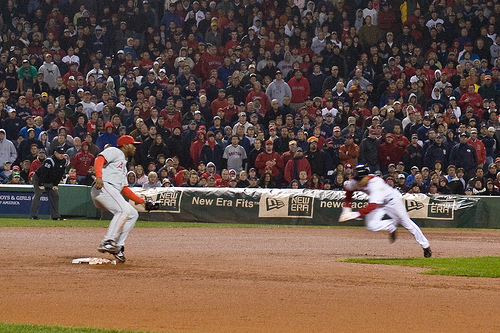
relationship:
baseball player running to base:
[338, 163, 433, 258] [71, 246, 118, 275]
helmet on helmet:
[351, 164, 371, 181] [351, 164, 371, 181]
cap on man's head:
[116, 135, 141, 147] [116, 131, 139, 158]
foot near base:
[94, 239, 130, 268] [67, 256, 114, 270]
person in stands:
[282, 138, 316, 188] [4, 1, 497, 230]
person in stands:
[257, 146, 279, 188] [4, 1, 497, 230]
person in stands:
[220, 136, 250, 172] [4, 1, 497, 230]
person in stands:
[260, 65, 299, 125] [4, 1, 497, 230]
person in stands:
[283, 58, 318, 108] [4, 1, 497, 230]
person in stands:
[307, 62, 329, 105] [63, 8, 474, 175]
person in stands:
[453, 79, 479, 107] [6, 6, 490, 191]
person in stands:
[35, 49, 65, 100] [16, 11, 467, 181]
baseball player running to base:
[338, 163, 433, 258] [74, 250, 125, 269]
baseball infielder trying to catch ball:
[90, 134, 147, 263] [258, 93, 285, 111]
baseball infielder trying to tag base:
[90, 134, 147, 263] [69, 250, 122, 270]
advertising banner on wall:
[61, 180, 482, 230] [3, 180, 498, 231]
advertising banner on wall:
[3, 186, 58, 220] [3, 180, 498, 231]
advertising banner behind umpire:
[3, 186, 58, 220] [3, 180, 498, 229]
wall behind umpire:
[3, 180, 498, 231] [3, 180, 498, 229]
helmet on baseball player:
[344, 164, 374, 180] [338, 163, 433, 258]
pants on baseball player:
[352, 190, 450, 274] [335, 163, 446, 267]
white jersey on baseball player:
[345, 180, 402, 221] [314, 142, 463, 300]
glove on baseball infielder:
[147, 193, 170, 212] [88, 123, 149, 269]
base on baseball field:
[69, 257, 117, 266] [14, 207, 498, 329]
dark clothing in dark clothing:
[29, 145, 70, 221] [28, 140, 70, 218]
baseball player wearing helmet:
[338, 163, 433, 258] [346, 164, 376, 184]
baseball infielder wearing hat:
[90, 134, 147, 263] [114, 133, 136, 145]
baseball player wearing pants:
[338, 163, 433, 258] [369, 197, 431, 249]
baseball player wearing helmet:
[338, 163, 433, 258] [351, 163, 368, 176]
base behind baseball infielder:
[69, 258, 108, 266] [90, 134, 147, 263]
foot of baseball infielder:
[97, 239, 127, 262] [90, 134, 147, 263]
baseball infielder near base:
[90, 134, 147, 263] [71, 257, 113, 266]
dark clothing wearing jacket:
[29, 145, 70, 221] [33, 154, 66, 187]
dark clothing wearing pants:
[29, 145, 70, 221] [29, 182, 59, 221]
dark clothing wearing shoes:
[29, 145, 70, 221] [29, 212, 63, 221]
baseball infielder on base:
[90, 134, 147, 263] [66, 252, 110, 264]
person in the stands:
[216, 136, 258, 170] [57, 50, 477, 175]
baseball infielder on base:
[90, 134, 147, 263] [67, 254, 118, 267]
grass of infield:
[340, 237, 493, 279] [341, 207, 497, 302]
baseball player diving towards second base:
[314, 165, 430, 254] [292, 235, 331, 282]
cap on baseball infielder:
[115, 134, 145, 147] [90, 131, 152, 261]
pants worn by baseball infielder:
[90, 183, 137, 245] [90, 134, 147, 263]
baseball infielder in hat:
[90, 134, 147, 263] [113, 135, 143, 145]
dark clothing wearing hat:
[29, 145, 70, 221] [52, 144, 66, 154]